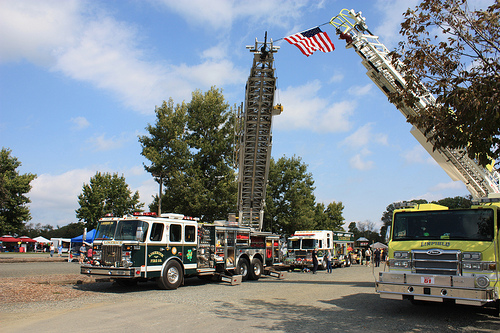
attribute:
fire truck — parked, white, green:
[81, 11, 285, 288]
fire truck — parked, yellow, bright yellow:
[329, 8, 500, 314]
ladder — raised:
[237, 32, 283, 231]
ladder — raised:
[330, 9, 500, 202]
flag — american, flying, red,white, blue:
[285, 25, 335, 55]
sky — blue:
[1, 0, 500, 236]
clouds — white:
[0, 0, 500, 238]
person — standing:
[312, 246, 320, 272]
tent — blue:
[67, 230, 111, 262]